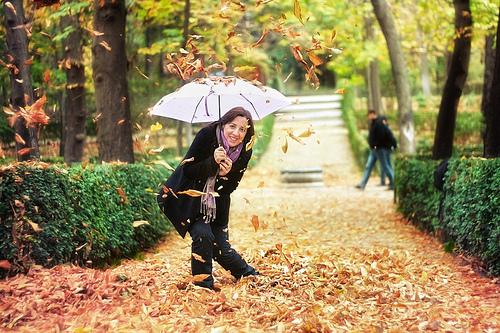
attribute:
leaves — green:
[288, 0, 345, 58]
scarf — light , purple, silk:
[196, 127, 239, 224]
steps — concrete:
[269, 97, 348, 144]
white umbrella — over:
[146, 72, 293, 125]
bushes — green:
[2, 143, 206, 272]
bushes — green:
[384, 147, 498, 249]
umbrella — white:
[147, 77, 288, 124]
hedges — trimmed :
[5, 155, 186, 293]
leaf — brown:
[275, 237, 289, 259]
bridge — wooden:
[247, 77, 379, 176]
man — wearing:
[352, 106, 397, 188]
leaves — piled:
[295, 198, 370, 299]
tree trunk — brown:
[89, 5, 143, 162]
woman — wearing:
[157, 106, 279, 293]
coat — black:
[156, 119, 255, 240]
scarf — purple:
[197, 125, 259, 218]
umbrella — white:
[147, 58, 299, 142]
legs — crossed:
[165, 202, 270, 294]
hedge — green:
[395, 149, 494, 270]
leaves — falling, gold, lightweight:
[2, 2, 358, 283]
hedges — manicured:
[446, 153, 498, 245]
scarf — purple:
[208, 121, 240, 220]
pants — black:
[172, 197, 264, 292]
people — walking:
[365, 107, 407, 195]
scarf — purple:
[199, 129, 243, 226]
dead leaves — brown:
[1, 194, 498, 328]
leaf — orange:
[178, 187, 215, 203]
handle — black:
[215, 93, 228, 166]